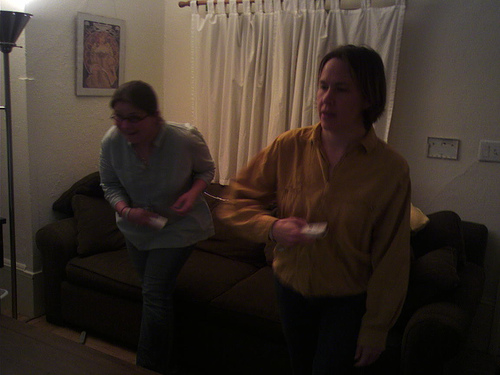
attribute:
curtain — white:
[181, 0, 414, 220]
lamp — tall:
[1, 6, 47, 328]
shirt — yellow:
[218, 114, 427, 342]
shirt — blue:
[88, 114, 229, 261]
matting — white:
[75, 10, 126, 99]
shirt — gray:
[97, 120, 217, 249]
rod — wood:
[176, 0, 299, 6]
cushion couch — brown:
[36, 166, 489, 373]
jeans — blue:
[121, 237, 194, 373]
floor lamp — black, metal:
[0, 9, 32, 319]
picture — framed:
[73, 12, 124, 95]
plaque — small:
[422, 133, 461, 163]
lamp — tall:
[0, 9, 34, 319]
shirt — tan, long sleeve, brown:
[210, 123, 410, 350]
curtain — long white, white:
[189, 1, 407, 186]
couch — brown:
[33, 169, 490, 373]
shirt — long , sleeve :
[84, 113, 230, 242]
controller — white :
[124, 201, 204, 247]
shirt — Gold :
[263, 137, 407, 347]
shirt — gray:
[66, 133, 229, 234]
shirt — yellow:
[216, 103, 436, 322]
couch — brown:
[30, 136, 498, 343]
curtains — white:
[179, 0, 411, 207]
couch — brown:
[52, 148, 484, 371]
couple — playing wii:
[74, 36, 420, 370]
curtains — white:
[164, 0, 416, 228]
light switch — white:
[467, 129, 498, 186]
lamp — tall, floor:
[2, 9, 37, 320]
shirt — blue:
[92, 115, 221, 255]